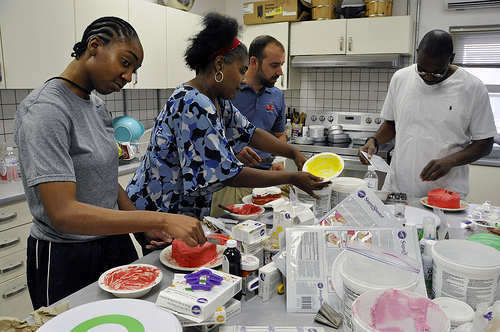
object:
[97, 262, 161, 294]
container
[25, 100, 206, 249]
arm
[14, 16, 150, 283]
lady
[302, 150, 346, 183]
container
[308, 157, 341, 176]
stain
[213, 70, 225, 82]
earring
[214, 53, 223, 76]
ear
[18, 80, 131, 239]
t-shirt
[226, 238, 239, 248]
bottle top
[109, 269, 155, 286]
stain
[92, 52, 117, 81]
cheek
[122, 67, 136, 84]
nose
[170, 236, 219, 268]
cake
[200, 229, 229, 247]
iced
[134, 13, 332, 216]
woman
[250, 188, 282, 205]
cake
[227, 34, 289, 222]
man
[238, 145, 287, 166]
iced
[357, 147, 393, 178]
paper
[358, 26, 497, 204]
man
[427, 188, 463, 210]
cake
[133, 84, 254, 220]
top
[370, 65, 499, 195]
t-shirt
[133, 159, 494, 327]
cooking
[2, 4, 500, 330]
kitchen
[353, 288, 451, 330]
bucket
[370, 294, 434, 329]
pink icing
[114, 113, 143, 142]
bowl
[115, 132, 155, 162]
dish drain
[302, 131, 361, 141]
back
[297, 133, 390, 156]
stove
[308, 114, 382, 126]
control knobs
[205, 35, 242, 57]
hair band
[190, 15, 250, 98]
woman's head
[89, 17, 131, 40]
corn rows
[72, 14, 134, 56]
hair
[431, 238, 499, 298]
plastic bowl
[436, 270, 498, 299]
writing on it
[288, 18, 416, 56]
cabinet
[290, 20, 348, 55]
door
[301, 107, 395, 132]
oven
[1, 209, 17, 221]
silver handle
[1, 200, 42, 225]
drawer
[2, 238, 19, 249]
silver handle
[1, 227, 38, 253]
drawer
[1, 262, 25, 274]
silver handle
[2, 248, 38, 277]
drawer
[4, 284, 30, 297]
silver handle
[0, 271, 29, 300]
drawer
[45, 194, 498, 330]
table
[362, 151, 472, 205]
down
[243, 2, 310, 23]
carboard box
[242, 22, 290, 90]
cabinet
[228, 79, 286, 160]
shirt